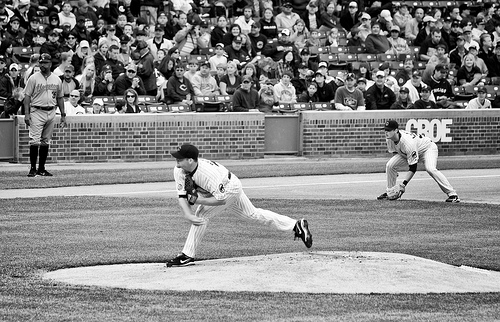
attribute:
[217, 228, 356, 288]
mound — here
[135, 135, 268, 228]
pitcher — throwing, bent, pitching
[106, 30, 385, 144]
spectators — sitting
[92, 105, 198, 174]
wall — brick, here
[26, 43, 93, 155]
coach — standing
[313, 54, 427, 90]
seats — empty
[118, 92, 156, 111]
woman — wearing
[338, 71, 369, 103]
man — wearing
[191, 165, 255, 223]
suit — pinstriped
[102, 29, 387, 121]
audience — watching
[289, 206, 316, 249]
shoes — nike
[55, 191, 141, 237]
grass — manicured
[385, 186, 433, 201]
mitt — worn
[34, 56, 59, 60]
helmet — black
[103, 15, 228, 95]
people — watching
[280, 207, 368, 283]
sneaker — white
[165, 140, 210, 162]
hat — worn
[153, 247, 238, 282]
shoe — black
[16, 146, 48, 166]
sock — black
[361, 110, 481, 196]
baseman — bent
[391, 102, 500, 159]
croe — written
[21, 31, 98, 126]
teammate — opposing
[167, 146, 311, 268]
player — throwing, poised, standing, crouching